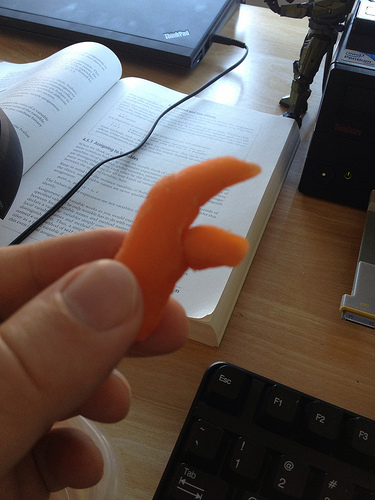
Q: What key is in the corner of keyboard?
A: Esc.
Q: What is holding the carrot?
A: Hand.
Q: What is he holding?
A: Carrot.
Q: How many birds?
A: None.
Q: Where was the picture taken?
A: Desk.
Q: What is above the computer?
A: Book.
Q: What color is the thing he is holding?
A: Orange.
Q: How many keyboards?
A: 1.